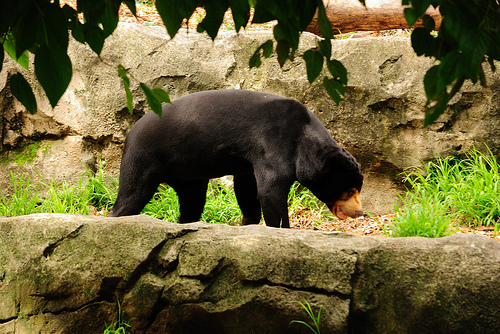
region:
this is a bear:
[85, 38, 382, 243]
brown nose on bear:
[314, 171, 377, 238]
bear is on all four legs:
[65, 65, 410, 271]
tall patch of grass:
[377, 128, 499, 256]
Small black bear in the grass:
[93, 71, 415, 227]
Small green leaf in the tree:
[111, 61, 142, 114]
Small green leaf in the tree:
[138, 79, 170, 114]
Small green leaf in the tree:
[293, 41, 321, 84]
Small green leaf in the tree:
[322, 52, 349, 115]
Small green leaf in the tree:
[250, 39, 274, 71]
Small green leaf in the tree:
[418, 23, 464, 113]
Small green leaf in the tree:
[30, 39, 75, 109]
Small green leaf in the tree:
[43, 11, 113, 46]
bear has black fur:
[112, 88, 363, 231]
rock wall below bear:
[1, 209, 498, 331]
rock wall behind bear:
[0, 16, 499, 208]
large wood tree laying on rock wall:
[53, 0, 498, 35]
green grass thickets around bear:
[1, 145, 499, 238]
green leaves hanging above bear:
[0, 0, 499, 122]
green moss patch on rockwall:
[2, 137, 47, 174]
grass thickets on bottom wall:
[104, 296, 326, 332]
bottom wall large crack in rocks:
[0, 256, 364, 331]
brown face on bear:
[332, 180, 365, 223]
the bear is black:
[88, 62, 377, 252]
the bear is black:
[103, 53, 368, 241]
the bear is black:
[94, 60, 394, 254]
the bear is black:
[88, 55, 400, 277]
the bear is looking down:
[291, 103, 388, 263]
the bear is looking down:
[272, 108, 380, 250]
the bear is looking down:
[270, 99, 370, 230]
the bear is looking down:
[288, 114, 379, 239]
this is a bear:
[63, 17, 393, 267]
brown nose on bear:
[323, 175, 374, 229]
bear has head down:
[285, 97, 393, 240]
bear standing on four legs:
[80, 69, 419, 293]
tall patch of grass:
[389, 122, 496, 248]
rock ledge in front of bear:
[2, 178, 490, 331]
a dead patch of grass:
[288, 193, 405, 250]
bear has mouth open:
[328, 189, 375, 229]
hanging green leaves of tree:
[1, 1, 498, 131]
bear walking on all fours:
[110, 87, 364, 226]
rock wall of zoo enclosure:
[1, 212, 498, 331]